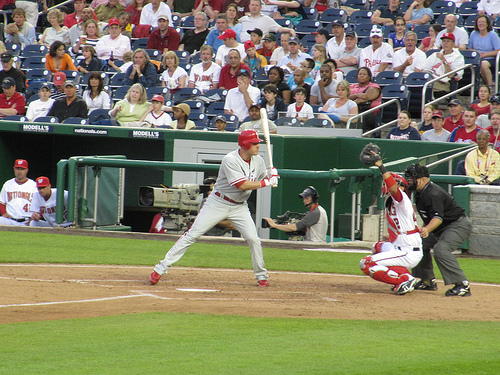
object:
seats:
[296, 18, 322, 35]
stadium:
[3, 0, 499, 373]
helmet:
[238, 130, 264, 149]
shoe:
[257, 280, 269, 287]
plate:
[176, 287, 224, 292]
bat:
[259, 107, 274, 169]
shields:
[371, 239, 393, 253]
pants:
[412, 213, 473, 285]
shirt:
[414, 180, 466, 237]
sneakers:
[392, 273, 416, 295]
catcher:
[359, 142, 424, 295]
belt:
[398, 246, 419, 251]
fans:
[321, 81, 360, 124]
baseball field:
[0, 253, 334, 329]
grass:
[175, 319, 300, 367]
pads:
[369, 264, 398, 278]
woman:
[171, 102, 195, 129]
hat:
[174, 103, 191, 116]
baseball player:
[148, 121, 281, 288]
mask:
[405, 170, 421, 191]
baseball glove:
[357, 141, 382, 165]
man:
[463, 130, 500, 183]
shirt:
[464, 150, 499, 183]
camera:
[138, 184, 211, 234]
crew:
[262, 185, 328, 242]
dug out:
[200, 177, 237, 237]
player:
[28, 177, 69, 226]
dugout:
[3, 123, 466, 241]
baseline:
[0, 294, 108, 309]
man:
[0, 159, 37, 226]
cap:
[14, 159, 29, 169]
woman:
[485, 111, 500, 151]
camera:
[261, 210, 307, 230]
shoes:
[148, 271, 162, 285]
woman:
[44, 41, 79, 74]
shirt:
[45, 53, 76, 71]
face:
[310, 63, 339, 105]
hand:
[318, 78, 329, 86]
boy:
[213, 115, 227, 131]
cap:
[214, 115, 226, 123]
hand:
[366, 150, 383, 167]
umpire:
[403, 161, 471, 297]